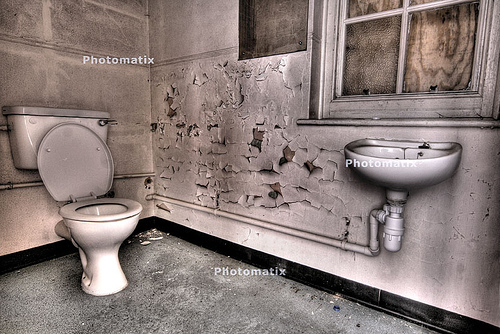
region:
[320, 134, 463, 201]
white wash basin fixed in the wall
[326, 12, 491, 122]
window in the wall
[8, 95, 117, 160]
white color flush tank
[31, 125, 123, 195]
white color toilet lid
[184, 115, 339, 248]
old wall in the toilet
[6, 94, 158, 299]
white color toilet with flush tank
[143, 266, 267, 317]
floor of the toilet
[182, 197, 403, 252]
water pipe attached in the wall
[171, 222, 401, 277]
wall and the floor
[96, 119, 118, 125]
flush control of the toilet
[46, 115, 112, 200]
A toilet lid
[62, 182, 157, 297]
A toilet seat in the bathroom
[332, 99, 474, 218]
A sink in the bathroom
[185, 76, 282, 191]
A wall in the toilet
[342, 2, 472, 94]
A window in the room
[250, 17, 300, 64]
A mirror in the photo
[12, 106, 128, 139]
A toilet tank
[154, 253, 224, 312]
A concrete floor in the room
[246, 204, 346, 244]
A water pipe in the room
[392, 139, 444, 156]
A tap on the sink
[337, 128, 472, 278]
a sink in a bathroom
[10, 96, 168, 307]
a toilet in a bathroom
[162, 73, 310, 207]
paint peeling off the walls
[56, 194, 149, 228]
a toilet seat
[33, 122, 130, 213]
the lid of the toilet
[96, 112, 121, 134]
the handle of the toilet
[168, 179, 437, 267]
plumbing going to the sink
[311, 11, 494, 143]
a window in the bathroom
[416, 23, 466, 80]
plywood covering the window in the bathroom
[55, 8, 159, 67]
bricks on the wall of the bathroom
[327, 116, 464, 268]
the sink is white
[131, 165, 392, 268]
the pipe is along the wall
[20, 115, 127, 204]
the lid is up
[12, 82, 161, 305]
the toilet is white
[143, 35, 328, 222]
the wall is cracked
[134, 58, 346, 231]
the wall is dirty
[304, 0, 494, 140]
the window is closed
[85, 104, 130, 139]
the toilet handle is silver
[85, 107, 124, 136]
the handle is made of metal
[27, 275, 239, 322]
the floor is grey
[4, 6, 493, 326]
A picture of a restroom.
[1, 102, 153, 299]
A toilet in the restroom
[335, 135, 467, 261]
A sink in the restroom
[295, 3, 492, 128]
A boarded up window in the restroom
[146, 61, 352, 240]
Peeling paint on the wall of the restroom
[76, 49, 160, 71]
A watermark on the photograph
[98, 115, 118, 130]
The toilet's flush handle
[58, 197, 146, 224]
A toilet seat on the toilet in the restroom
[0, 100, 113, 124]
The toilet tank cover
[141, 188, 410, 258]
A pipe running along the wall to the sink